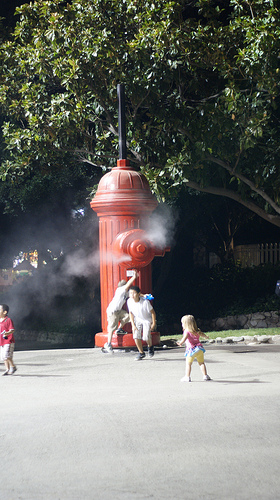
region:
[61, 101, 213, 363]
a large fire hydrant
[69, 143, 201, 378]
a large red fire hydrant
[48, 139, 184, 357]
a red fire hydrant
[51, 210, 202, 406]
steam coming off the fire hydrant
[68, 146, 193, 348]
steam coming off the hydrant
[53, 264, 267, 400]
kids playing on the road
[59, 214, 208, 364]
a kid crawling on the fire hydrant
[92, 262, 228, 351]
a kid climbing the fire hydrant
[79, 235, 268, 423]
kids playing during the day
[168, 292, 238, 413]
a young girl wearing yellow shorts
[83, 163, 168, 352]
enormous red fire hydrant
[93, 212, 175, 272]
steam or water coming out of fire hydrant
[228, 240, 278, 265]
white picket fence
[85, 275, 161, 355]
two boys playing with a fire hydrant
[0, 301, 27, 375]
small boy in red t-shirt walking away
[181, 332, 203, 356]
pink shirt on a little girl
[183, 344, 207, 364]
yellow shorts on a little girl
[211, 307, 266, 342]
stone wall on side of street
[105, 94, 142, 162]
black pole extending from fire hydrant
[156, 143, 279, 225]
large tree in the background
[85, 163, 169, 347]
an oversized red fire hydrant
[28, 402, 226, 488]
a concrete play platform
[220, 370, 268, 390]
the shadow of a little girl on the concrete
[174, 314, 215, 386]
a young blonde girl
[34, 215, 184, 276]
steam coming from the fake fire hydrant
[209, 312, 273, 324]
a stone border behind the hydrant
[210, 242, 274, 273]
a white wooden picket fence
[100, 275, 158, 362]
two young boys playing in front of the hydrant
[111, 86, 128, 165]
the large metal pole at the top of the hydrant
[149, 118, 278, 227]
a huge green tree behind the play area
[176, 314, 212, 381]
little blonde girl in pink top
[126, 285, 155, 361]
young boy running in black sneakers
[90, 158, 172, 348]
a giant red fire hydrant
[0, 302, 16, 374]
a boy in a red shirt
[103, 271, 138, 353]
a boy in shorts playing with giant fire hydrant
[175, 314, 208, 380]
a little girl in yellow shorts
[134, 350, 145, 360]
a boy's right foot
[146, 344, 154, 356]
a boy's left foot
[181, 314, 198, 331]
a girls blonde hair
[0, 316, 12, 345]
a boy's red shirt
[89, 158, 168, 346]
a large red fire hydrant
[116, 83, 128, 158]
a tall black pole on top of a fire hydrant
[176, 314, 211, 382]
a young girl with blond hair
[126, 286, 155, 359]
a young boy with black hair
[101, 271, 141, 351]
a young boy climbing on a fire hydrant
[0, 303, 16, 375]
a small boy wearing a red shirt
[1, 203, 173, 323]
steam coming out of the fire hydrant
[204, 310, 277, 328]
a stone wall beside the fire hydrant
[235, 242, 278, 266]
a wood picket fence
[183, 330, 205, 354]
a pink and blue shirt on a little girl